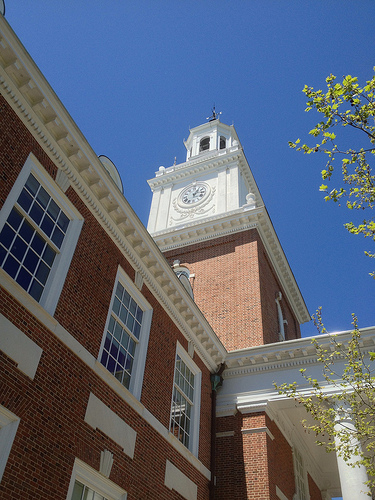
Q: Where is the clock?
A: On the tower.